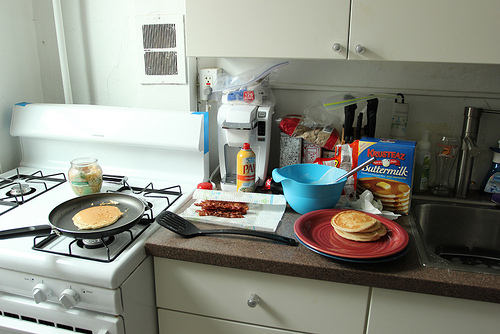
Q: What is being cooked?
A: Pancake.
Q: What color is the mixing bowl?
A: Blue.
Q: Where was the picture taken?
A: In a kitchen.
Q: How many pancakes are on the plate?
A: 4.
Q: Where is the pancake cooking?
A: In a pan.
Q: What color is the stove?
A: White.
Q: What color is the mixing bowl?
A: Blue.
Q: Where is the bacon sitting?
A: On a paper towel.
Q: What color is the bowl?
A: Blue.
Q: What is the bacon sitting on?
A: A paper towel.